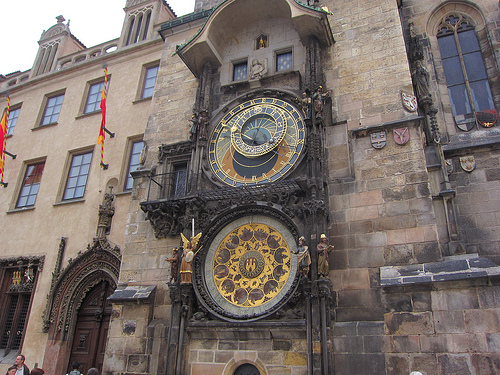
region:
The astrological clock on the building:
[161, 70, 341, 327]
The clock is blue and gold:
[209, 93, 309, 150]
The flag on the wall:
[93, 57, 125, 172]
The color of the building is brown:
[20, 70, 95, 210]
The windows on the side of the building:
[1, 45, 168, 226]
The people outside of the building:
[6, 343, 139, 373]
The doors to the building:
[41, 246, 126, 372]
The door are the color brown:
[60, 278, 114, 373]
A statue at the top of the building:
[239, 52, 281, 81]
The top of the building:
[18, 1, 215, 65]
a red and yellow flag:
[94, 82, 116, 156]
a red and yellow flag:
[85, 56, 125, 170]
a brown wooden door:
[53, 285, 104, 372]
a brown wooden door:
[63, 273, 126, 373]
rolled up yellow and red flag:
[97, 60, 108, 168]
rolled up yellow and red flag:
[0, 95, 10, 186]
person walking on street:
[4, 353, 32, 373]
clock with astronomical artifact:
[202, 88, 308, 188]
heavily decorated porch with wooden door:
[42, 189, 123, 374]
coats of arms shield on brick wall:
[367, 128, 386, 150]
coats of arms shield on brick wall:
[391, 125, 408, 147]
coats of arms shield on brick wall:
[399, 88, 420, 113]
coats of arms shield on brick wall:
[458, 153, 475, 172]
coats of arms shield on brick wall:
[472, 108, 496, 130]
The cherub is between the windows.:
[230, 45, 311, 90]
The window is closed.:
[221, 47, 248, 92]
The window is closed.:
[270, 48, 297, 73]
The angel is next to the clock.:
[164, 215, 209, 307]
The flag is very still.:
[89, 54, 116, 181]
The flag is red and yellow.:
[89, 55, 117, 190]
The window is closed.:
[27, 85, 71, 134]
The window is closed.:
[11, 152, 48, 215]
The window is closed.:
[55, 134, 92, 216]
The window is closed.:
[134, 57, 161, 104]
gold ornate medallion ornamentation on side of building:
[195, 201, 302, 319]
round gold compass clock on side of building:
[203, 89, 310, 194]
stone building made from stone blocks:
[99, 0, 495, 374]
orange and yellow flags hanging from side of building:
[94, 55, 128, 167]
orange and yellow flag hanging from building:
[0, 87, 29, 180]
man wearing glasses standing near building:
[3, 350, 34, 372]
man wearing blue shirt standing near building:
[4, 351, 31, 373]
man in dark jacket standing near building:
[4, 348, 36, 371]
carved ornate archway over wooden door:
[30, 176, 146, 373]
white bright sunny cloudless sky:
[6, 0, 196, 72]